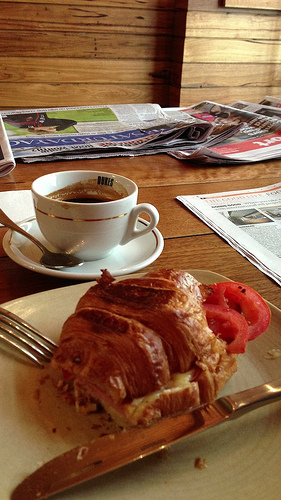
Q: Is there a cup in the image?
A: Yes, there is a cup.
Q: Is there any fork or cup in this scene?
A: Yes, there is a cup.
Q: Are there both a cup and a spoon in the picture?
A: Yes, there are both a cup and a spoon.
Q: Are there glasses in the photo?
A: No, there are no glasses.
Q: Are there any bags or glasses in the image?
A: No, there are no glasses or bags.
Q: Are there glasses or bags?
A: No, there are no glasses or bags.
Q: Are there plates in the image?
A: Yes, there is a plate.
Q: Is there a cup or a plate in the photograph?
A: Yes, there is a plate.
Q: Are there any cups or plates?
A: Yes, there is a plate.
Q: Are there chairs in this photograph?
A: No, there are no chairs.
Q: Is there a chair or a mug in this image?
A: No, there are no chairs or mugs.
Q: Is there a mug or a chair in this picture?
A: No, there are no chairs or mugs.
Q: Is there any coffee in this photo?
A: Yes, there is coffee.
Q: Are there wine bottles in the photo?
A: No, there are no wine bottles.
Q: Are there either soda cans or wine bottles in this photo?
A: No, there are no wine bottles or soda cans.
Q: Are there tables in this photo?
A: Yes, there is a table.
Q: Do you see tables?
A: Yes, there is a table.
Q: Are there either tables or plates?
A: Yes, there is a table.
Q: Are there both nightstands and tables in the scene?
A: No, there is a table but no nightstands.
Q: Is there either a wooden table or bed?
A: Yes, there is a wood table.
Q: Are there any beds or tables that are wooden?
A: Yes, the table is wooden.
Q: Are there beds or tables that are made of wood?
A: Yes, the table is made of wood.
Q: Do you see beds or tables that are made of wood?
A: Yes, the table is made of wood.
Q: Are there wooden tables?
A: Yes, there is a wood table.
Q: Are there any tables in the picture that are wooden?
A: Yes, there is a table that is wooden.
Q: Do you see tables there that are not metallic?
A: Yes, there is a wooden table.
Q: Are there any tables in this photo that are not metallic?
A: Yes, there is a wooden table.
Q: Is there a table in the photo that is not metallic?
A: Yes, there is a wooden table.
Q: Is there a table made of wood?
A: Yes, there is a table that is made of wood.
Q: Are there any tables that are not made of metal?
A: Yes, there is a table that is made of wood.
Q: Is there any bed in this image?
A: No, there are no beds.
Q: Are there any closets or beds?
A: No, there are no beds or closets.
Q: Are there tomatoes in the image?
A: Yes, there is a tomato.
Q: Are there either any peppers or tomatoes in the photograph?
A: Yes, there is a tomato.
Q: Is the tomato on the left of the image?
A: No, the tomato is on the right of the image.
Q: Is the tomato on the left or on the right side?
A: The tomato is on the right of the image.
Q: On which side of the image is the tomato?
A: The tomato is on the right of the image.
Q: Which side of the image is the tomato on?
A: The tomato is on the right of the image.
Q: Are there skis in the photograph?
A: No, there are no skis.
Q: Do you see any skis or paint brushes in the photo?
A: No, there are no skis or paint brushes.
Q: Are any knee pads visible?
A: No, there are no knee pads.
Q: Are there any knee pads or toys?
A: No, there are no knee pads or toys.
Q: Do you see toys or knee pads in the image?
A: No, there are no knee pads or toys.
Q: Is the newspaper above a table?
A: Yes, the newspaper is above a table.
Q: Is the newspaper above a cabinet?
A: No, the newspaper is above a table.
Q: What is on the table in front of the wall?
A: The newspaper is on the table.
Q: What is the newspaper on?
A: The newspaper is on the table.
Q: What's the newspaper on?
A: The newspaper is on the table.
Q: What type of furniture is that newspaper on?
A: The newspaper is on the table.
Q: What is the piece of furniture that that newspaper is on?
A: The piece of furniture is a table.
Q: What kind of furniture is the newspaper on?
A: The newspaper is on the table.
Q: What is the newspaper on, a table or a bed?
A: The newspaper is on a table.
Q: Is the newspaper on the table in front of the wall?
A: Yes, the newspaper is on the table.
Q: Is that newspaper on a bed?
A: No, the newspaper is on the table.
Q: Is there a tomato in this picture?
A: Yes, there is a tomato.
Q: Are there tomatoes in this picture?
A: Yes, there is a tomato.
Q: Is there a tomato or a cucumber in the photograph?
A: Yes, there is a tomato.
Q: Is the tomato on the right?
A: Yes, the tomato is on the right of the image.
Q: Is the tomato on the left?
A: No, the tomato is on the right of the image.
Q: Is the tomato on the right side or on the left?
A: The tomato is on the right of the image.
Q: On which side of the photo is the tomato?
A: The tomato is on the right of the image.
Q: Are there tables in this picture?
A: Yes, there is a table.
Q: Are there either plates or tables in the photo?
A: Yes, there is a table.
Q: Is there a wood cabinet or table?
A: Yes, there is a wood table.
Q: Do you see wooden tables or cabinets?
A: Yes, there is a wood table.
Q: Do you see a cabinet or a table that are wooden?
A: Yes, the table is wooden.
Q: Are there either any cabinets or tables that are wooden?
A: Yes, the table is wooden.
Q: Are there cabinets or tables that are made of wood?
A: Yes, the table is made of wood.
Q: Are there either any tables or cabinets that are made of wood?
A: Yes, the table is made of wood.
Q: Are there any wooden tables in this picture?
A: Yes, there is a wood table.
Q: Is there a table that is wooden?
A: Yes, there is a table that is wooden.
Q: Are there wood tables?
A: Yes, there is a table that is made of wood.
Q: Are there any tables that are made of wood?
A: Yes, there is a table that is made of wood.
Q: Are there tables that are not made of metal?
A: Yes, there is a table that is made of wood.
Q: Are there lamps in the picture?
A: No, there are no lamps.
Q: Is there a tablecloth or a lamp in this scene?
A: No, there are no lamps or tablecloths.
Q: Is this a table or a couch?
A: This is a table.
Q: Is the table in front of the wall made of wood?
A: Yes, the table is made of wood.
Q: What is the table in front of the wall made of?
A: The table is made of wood.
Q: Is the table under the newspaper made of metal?
A: No, the table is made of wood.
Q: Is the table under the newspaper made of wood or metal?
A: The table is made of wood.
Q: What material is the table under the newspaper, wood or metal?
A: The table is made of wood.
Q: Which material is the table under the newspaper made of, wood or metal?
A: The table is made of wood.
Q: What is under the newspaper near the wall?
A: The table is under the newspaper.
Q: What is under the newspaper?
A: The table is under the newspaper.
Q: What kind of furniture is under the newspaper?
A: The piece of furniture is a table.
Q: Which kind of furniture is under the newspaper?
A: The piece of furniture is a table.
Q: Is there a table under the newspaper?
A: Yes, there is a table under the newspaper.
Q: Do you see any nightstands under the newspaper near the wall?
A: No, there is a table under the newspaper.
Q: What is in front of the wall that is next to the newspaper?
A: The table is in front of the wall.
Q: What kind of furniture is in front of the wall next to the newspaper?
A: The piece of furniture is a table.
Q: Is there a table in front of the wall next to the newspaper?
A: Yes, there is a table in front of the wall.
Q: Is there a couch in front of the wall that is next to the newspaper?
A: No, there is a table in front of the wall.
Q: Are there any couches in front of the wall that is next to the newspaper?
A: No, there is a table in front of the wall.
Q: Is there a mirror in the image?
A: No, there are no mirrors.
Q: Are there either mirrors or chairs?
A: No, there are no mirrors or chairs.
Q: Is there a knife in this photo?
A: Yes, there is a knife.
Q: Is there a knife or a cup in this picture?
A: Yes, there is a knife.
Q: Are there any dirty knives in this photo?
A: Yes, there is a dirty knife.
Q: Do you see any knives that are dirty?
A: Yes, there is a knife that is dirty.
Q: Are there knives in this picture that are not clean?
A: Yes, there is a dirty knife.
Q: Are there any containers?
A: No, there are no containers.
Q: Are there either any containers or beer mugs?
A: No, there are no containers or beer mugs.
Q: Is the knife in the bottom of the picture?
A: Yes, the knife is in the bottom of the image.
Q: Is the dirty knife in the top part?
A: No, the knife is in the bottom of the image.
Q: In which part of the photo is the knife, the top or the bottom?
A: The knife is in the bottom of the image.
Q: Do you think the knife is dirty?
A: Yes, the knife is dirty.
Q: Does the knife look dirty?
A: Yes, the knife is dirty.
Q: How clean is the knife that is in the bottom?
A: The knife is dirty.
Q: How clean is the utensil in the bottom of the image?
A: The knife is dirty.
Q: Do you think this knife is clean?
A: No, the knife is dirty.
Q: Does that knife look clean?
A: No, the knife is dirty.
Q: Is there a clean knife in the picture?
A: No, there is a knife but it is dirty.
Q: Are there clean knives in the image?
A: No, there is a knife but it is dirty.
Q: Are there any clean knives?
A: No, there is a knife but it is dirty.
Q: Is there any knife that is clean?
A: No, there is a knife but it is dirty.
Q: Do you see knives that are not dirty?
A: No, there is a knife but it is dirty.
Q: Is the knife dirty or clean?
A: The knife is dirty.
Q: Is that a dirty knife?
A: Yes, that is a dirty knife.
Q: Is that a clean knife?
A: No, that is a dirty knife.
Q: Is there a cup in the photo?
A: Yes, there is a cup.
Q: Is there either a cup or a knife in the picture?
A: Yes, there is a cup.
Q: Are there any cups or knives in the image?
A: Yes, there is a cup.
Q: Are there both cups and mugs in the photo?
A: No, there is a cup but no mugs.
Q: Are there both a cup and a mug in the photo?
A: No, there is a cup but no mugs.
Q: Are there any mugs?
A: No, there are no mugs.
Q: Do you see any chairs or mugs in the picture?
A: No, there are no mugs or chairs.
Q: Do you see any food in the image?
A: Yes, there is food.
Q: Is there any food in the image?
A: Yes, there is food.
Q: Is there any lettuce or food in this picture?
A: Yes, there is food.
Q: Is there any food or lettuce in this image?
A: Yes, there is food.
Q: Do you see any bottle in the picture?
A: No, there are no bottles.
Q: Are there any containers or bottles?
A: No, there are no bottles or containers.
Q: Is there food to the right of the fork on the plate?
A: Yes, there is food to the right of the fork.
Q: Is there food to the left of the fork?
A: No, the food is to the right of the fork.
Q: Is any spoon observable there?
A: Yes, there is a spoon.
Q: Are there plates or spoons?
A: Yes, there is a spoon.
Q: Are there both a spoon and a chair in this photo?
A: No, there is a spoon but no chairs.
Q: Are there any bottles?
A: No, there are no bottles.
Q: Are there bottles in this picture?
A: No, there are no bottles.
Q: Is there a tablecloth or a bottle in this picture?
A: No, there are no bottles or tablecloths.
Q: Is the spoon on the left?
A: Yes, the spoon is on the left of the image.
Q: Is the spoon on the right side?
A: No, the spoon is on the left of the image.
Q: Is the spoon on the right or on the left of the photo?
A: The spoon is on the left of the image.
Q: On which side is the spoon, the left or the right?
A: The spoon is on the left of the image.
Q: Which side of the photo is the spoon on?
A: The spoon is on the left of the image.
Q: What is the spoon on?
A: The spoon is on the plate.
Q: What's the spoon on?
A: The spoon is on the plate.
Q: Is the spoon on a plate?
A: Yes, the spoon is on a plate.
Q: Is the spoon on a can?
A: No, the spoon is on a plate.